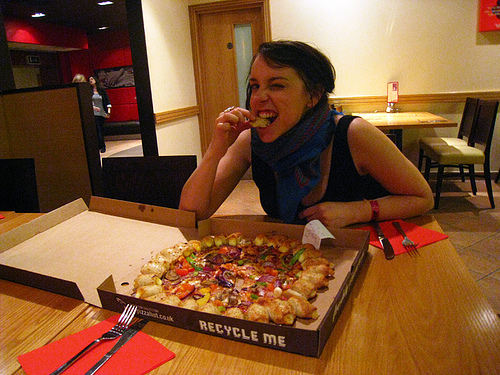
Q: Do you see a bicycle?
A: No, there are no bicycles.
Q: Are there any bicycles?
A: No, there are no bicycles.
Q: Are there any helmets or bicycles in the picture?
A: No, there are no bicycles or helmets.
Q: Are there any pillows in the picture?
A: No, there are no pillows.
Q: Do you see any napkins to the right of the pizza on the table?
A: Yes, there is a napkin to the right of the pizza.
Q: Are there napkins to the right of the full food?
A: Yes, there is a napkin to the right of the pizza.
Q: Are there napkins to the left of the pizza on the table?
A: No, the napkin is to the right of the pizza.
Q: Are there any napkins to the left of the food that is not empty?
A: No, the napkin is to the right of the pizza.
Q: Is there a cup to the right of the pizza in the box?
A: No, there is a napkin to the right of the pizza.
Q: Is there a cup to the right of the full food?
A: No, there is a napkin to the right of the pizza.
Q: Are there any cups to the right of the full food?
A: No, there is a napkin to the right of the pizza.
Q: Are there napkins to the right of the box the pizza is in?
A: Yes, there is a napkin to the right of the box.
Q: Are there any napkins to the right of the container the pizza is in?
A: Yes, there is a napkin to the right of the box.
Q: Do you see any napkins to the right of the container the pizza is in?
A: Yes, there is a napkin to the right of the box.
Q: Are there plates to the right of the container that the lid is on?
A: No, there is a napkin to the right of the box.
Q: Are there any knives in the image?
A: Yes, there is a knife.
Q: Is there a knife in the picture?
A: Yes, there is a knife.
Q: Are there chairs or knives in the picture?
A: Yes, there is a knife.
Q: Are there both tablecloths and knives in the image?
A: No, there is a knife but no tablecloths.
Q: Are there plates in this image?
A: No, there are no plates.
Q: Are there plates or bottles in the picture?
A: No, there are no plates or bottles.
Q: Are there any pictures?
A: No, there are no pictures.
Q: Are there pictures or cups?
A: No, there are no pictures or cups.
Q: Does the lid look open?
A: Yes, the lid is open.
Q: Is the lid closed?
A: No, the lid is open.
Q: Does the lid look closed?
A: No, the lid is open.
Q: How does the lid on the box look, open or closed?
A: The lid is open.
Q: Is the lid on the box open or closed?
A: The lid is open.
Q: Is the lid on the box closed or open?
A: The lid is open.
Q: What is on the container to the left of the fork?
A: The lid is on the box.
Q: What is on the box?
A: The lid is on the box.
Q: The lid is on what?
A: The lid is on the box.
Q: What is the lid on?
A: The lid is on the box.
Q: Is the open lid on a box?
A: Yes, the lid is on a box.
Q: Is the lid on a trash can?
A: No, the lid is on a box.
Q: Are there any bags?
A: No, there are no bags.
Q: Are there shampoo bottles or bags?
A: No, there are no bags or shampoo bottles.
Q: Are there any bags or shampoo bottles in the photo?
A: No, there are no bags or shampoo bottles.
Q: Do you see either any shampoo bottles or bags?
A: No, there are no bags or shampoo bottles.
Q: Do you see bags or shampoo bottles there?
A: No, there are no bags or shampoo bottles.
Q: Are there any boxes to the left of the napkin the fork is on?
A: Yes, there is a box to the left of the napkin.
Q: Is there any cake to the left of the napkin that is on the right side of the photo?
A: No, there is a box to the left of the napkin.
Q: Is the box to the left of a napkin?
A: Yes, the box is to the left of a napkin.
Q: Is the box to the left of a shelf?
A: No, the box is to the left of a napkin.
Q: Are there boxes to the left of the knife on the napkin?
A: Yes, there is a box to the left of the knife.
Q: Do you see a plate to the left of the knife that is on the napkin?
A: No, there is a box to the left of the knife.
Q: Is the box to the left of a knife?
A: Yes, the box is to the left of a knife.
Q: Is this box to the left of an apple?
A: No, the box is to the left of a knife.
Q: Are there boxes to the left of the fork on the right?
A: Yes, there is a box to the left of the fork.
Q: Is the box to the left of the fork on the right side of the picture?
A: Yes, the box is to the left of the fork.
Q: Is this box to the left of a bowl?
A: No, the box is to the left of the fork.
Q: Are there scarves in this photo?
A: Yes, there is a scarf.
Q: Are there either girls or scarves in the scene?
A: Yes, there is a scarf.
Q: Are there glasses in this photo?
A: No, there are no glasses.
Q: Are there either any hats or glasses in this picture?
A: No, there are no glasses or hats.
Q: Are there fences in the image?
A: No, there are no fences.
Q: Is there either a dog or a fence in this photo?
A: No, there are no fences or dogs.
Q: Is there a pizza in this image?
A: Yes, there is a pizza.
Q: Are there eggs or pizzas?
A: Yes, there is a pizza.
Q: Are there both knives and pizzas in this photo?
A: Yes, there are both a pizza and a knife.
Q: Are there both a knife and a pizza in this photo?
A: Yes, there are both a pizza and a knife.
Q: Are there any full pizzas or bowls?
A: Yes, there is a full pizza.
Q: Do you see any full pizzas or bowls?
A: Yes, there is a full pizza.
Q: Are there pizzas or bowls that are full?
A: Yes, the pizza is full.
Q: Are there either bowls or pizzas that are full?
A: Yes, the pizza is full.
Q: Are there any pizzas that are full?
A: Yes, there is a full pizza.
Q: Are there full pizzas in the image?
A: Yes, there is a full pizza.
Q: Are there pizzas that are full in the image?
A: Yes, there is a full pizza.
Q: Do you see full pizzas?
A: Yes, there is a full pizza.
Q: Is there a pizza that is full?
A: Yes, there is a pizza that is full.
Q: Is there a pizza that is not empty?
A: Yes, there is an full pizza.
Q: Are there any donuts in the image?
A: No, there are no donuts.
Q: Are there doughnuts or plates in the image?
A: No, there are no doughnuts or plates.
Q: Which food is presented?
A: The food is a pizza.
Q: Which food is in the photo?
A: The food is a pizza.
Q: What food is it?
A: The food is a pizza.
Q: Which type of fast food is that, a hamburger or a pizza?
A: That is a pizza.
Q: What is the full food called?
A: The food is a pizza.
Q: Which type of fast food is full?
A: The fast food is a pizza.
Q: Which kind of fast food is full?
A: The fast food is a pizza.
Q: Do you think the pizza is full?
A: Yes, the pizza is full.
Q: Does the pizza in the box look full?
A: Yes, the pizza is full.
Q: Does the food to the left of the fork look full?
A: Yes, the pizza is full.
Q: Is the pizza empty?
A: No, the pizza is full.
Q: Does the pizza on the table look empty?
A: No, the pizza is full.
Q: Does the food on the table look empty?
A: No, the pizza is full.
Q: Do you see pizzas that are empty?
A: No, there is a pizza but it is full.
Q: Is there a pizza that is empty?
A: No, there is a pizza but it is full.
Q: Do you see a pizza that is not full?
A: No, there is a pizza but it is full.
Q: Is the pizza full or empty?
A: The pizza is full.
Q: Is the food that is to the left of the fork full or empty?
A: The pizza is full.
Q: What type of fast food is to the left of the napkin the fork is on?
A: The food is a pizza.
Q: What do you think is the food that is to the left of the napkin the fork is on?
A: The food is a pizza.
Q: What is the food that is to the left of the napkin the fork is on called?
A: The food is a pizza.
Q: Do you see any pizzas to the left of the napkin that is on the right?
A: Yes, there is a pizza to the left of the napkin.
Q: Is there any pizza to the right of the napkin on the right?
A: No, the pizza is to the left of the napkin.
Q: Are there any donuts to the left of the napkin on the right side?
A: No, there is a pizza to the left of the napkin.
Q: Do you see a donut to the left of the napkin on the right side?
A: No, there is a pizza to the left of the napkin.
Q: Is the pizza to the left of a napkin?
A: Yes, the pizza is to the left of a napkin.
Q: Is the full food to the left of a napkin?
A: Yes, the pizza is to the left of a napkin.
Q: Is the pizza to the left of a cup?
A: No, the pizza is to the left of a napkin.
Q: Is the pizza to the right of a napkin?
A: No, the pizza is to the left of a napkin.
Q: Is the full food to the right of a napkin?
A: No, the pizza is to the left of a napkin.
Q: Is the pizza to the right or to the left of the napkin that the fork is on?
A: The pizza is to the left of the napkin.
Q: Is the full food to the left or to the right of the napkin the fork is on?
A: The pizza is to the left of the napkin.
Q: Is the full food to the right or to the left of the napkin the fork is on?
A: The pizza is to the left of the napkin.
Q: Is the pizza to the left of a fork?
A: Yes, the pizza is to the left of a fork.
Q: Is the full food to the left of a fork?
A: Yes, the pizza is to the left of a fork.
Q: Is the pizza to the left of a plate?
A: No, the pizza is to the left of a fork.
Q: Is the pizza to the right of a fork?
A: No, the pizza is to the left of a fork.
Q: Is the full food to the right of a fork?
A: No, the pizza is to the left of a fork.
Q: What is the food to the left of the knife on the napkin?
A: The food is a pizza.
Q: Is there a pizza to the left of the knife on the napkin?
A: Yes, there is a pizza to the left of the knife.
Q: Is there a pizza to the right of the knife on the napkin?
A: No, the pizza is to the left of the knife.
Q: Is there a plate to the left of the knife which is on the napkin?
A: No, there is a pizza to the left of the knife.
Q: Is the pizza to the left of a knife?
A: Yes, the pizza is to the left of a knife.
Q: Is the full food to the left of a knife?
A: Yes, the pizza is to the left of a knife.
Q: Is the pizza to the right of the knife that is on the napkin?
A: No, the pizza is to the left of the knife.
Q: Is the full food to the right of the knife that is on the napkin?
A: No, the pizza is to the left of the knife.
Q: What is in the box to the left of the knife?
A: The pizza is in the box.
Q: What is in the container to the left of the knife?
A: The pizza is in the box.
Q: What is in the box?
A: The pizza is in the box.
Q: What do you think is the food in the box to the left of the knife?
A: The food is a pizza.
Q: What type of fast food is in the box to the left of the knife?
A: The food is a pizza.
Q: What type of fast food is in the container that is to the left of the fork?
A: The food is a pizza.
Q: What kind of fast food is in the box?
A: The food is a pizza.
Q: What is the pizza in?
A: The pizza is in the box.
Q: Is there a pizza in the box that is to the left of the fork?
A: Yes, there is a pizza in the box.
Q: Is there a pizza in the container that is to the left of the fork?
A: Yes, there is a pizza in the box.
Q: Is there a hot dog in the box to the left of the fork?
A: No, there is a pizza in the box.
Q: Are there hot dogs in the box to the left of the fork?
A: No, there is a pizza in the box.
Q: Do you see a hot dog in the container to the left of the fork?
A: No, there is a pizza in the box.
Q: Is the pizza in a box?
A: Yes, the pizza is in a box.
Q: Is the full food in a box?
A: Yes, the pizza is in a box.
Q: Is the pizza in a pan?
A: No, the pizza is in a box.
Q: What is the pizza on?
A: The pizza is on the table.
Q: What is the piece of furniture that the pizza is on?
A: The piece of furniture is a table.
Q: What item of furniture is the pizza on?
A: The pizza is on the table.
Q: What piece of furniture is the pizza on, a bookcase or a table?
A: The pizza is on a table.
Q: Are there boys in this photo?
A: No, there are no boys.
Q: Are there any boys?
A: No, there are no boys.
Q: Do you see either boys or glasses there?
A: No, there are no boys or glasses.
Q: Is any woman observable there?
A: Yes, there is a woman.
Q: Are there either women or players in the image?
A: Yes, there is a woman.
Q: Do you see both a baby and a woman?
A: No, there is a woman but no babies.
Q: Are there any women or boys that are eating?
A: Yes, the woman is eating.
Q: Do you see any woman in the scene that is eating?
A: Yes, there is a woman that is eating.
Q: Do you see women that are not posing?
A: Yes, there is a woman that is eating .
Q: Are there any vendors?
A: No, there are no vendors.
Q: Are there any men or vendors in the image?
A: No, there are no vendors or men.